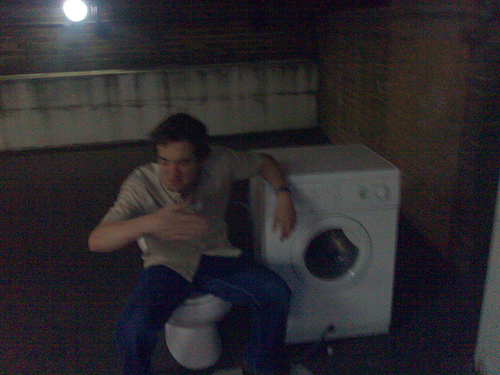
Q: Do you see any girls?
A: No, there are no girls.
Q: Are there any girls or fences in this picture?
A: No, there are no girls or fences.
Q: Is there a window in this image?
A: Yes, there is a window.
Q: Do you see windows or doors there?
A: Yes, there is a window.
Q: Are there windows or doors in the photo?
A: Yes, there is a window.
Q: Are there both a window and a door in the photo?
A: Yes, there are both a window and a door.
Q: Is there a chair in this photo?
A: No, there are no chairs.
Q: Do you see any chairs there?
A: No, there are no chairs.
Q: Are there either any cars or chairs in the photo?
A: No, there are no chairs or cars.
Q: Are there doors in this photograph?
A: Yes, there is a door.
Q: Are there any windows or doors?
A: Yes, there is a door.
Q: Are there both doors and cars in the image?
A: No, there is a door but no cars.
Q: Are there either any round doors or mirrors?
A: Yes, there is a round door.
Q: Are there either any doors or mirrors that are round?
A: Yes, the door is round.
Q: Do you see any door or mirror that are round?
A: Yes, the door is round.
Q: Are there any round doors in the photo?
A: Yes, there is a round door.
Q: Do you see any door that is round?
A: Yes, there is a door that is round.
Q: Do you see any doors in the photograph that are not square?
A: Yes, there is a round door.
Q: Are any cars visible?
A: No, there are no cars.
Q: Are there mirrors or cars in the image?
A: No, there are no cars or mirrors.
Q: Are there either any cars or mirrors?
A: No, there are no cars or mirrors.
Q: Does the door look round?
A: Yes, the door is round.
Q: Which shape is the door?
A: The door is round.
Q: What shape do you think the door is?
A: The door is round.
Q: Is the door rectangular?
A: No, the door is round.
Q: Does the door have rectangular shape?
A: No, the door is round.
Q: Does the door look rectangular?
A: No, the door is round.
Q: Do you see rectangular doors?
A: No, there is a door but it is round.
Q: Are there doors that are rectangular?
A: No, there is a door but it is round.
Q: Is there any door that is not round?
A: No, there is a door but it is round.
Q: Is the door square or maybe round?
A: The door is round.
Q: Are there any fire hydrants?
A: No, there are no fire hydrants.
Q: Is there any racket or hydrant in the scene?
A: No, there are no fire hydrants or rackets.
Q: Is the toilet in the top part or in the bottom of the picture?
A: The toilet is in the bottom of the image.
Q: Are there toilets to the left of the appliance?
A: Yes, there is a toilet to the left of the appliance.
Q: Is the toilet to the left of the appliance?
A: Yes, the toilet is to the left of the appliance.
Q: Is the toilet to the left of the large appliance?
A: Yes, the toilet is to the left of the appliance.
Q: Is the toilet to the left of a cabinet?
A: No, the toilet is to the left of the appliance.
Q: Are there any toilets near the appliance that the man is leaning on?
A: Yes, there is a toilet near the appliance.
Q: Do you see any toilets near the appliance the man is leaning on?
A: Yes, there is a toilet near the appliance.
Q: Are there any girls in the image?
A: No, there are no girls.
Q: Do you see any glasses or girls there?
A: No, there are no girls or glasses.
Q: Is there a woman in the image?
A: No, there are no women.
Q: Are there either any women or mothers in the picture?
A: No, there are no women or mothers.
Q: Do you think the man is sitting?
A: Yes, the man is sitting.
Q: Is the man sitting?
A: Yes, the man is sitting.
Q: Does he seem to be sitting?
A: Yes, the man is sitting.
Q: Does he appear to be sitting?
A: Yes, the man is sitting.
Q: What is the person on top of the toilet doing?
A: The man is sitting.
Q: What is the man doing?
A: The man is sitting.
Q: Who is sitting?
A: The man is sitting.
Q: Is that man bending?
A: No, the man is sitting.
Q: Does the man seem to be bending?
A: No, the man is sitting.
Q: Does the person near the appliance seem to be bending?
A: No, the man is sitting.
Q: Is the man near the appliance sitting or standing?
A: The man is sitting.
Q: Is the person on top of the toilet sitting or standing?
A: The man is sitting.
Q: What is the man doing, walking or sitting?
A: The man is sitting.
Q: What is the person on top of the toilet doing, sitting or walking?
A: The man is sitting.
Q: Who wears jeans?
A: The man wears jeans.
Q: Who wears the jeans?
A: The man wears jeans.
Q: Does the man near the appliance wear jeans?
A: Yes, the man wears jeans.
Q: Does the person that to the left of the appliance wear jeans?
A: Yes, the man wears jeans.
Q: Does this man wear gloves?
A: No, the man wears jeans.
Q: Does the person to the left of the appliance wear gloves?
A: No, the man wears jeans.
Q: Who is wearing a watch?
A: The man is wearing a watch.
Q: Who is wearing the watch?
A: The man is wearing a watch.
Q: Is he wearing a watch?
A: Yes, the man is wearing a watch.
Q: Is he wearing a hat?
A: No, the man is wearing a watch.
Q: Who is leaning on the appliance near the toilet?
A: The man is leaning on the appliance.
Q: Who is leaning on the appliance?
A: The man is leaning on the appliance.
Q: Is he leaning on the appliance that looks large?
A: Yes, the man is leaning on the appliance.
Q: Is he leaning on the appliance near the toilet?
A: Yes, the man is leaning on the appliance.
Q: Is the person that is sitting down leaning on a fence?
A: No, the man is leaning on the appliance.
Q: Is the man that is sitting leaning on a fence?
A: No, the man is leaning on the appliance.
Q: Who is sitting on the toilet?
A: The man is sitting on the toilet.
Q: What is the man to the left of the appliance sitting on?
A: The man is sitting on the toilet.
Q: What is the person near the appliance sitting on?
A: The man is sitting on the toilet.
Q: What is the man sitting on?
A: The man is sitting on the toilet.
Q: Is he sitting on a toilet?
A: Yes, the man is sitting on a toilet.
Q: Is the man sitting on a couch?
A: No, the man is sitting on a toilet.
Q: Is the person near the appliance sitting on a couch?
A: No, the man is sitting on a toilet.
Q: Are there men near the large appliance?
A: Yes, there is a man near the appliance.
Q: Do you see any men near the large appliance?
A: Yes, there is a man near the appliance.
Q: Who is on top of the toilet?
A: The man is on top of the toilet.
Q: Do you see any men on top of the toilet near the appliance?
A: Yes, there is a man on top of the toilet.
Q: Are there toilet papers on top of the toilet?
A: No, there is a man on top of the toilet.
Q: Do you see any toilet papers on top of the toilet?
A: No, there is a man on top of the toilet.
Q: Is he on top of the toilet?
A: Yes, the man is on top of the toilet.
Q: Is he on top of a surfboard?
A: No, the man is on top of the toilet.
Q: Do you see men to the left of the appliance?
A: Yes, there is a man to the left of the appliance.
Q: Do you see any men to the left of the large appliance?
A: Yes, there is a man to the left of the appliance.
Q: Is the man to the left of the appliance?
A: Yes, the man is to the left of the appliance.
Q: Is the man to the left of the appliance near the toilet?
A: Yes, the man is to the left of the appliance.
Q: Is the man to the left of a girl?
A: No, the man is to the left of the appliance.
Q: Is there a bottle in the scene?
A: No, there are no bottles.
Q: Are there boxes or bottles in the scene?
A: No, there are no bottles or boxes.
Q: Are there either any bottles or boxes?
A: No, there are no bottles or boxes.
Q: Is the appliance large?
A: Yes, the appliance is large.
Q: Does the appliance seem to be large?
A: Yes, the appliance is large.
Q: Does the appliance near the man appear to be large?
A: Yes, the appliance is large.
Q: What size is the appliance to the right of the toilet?
A: The appliance is large.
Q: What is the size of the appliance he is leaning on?
A: The appliance is large.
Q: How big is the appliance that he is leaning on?
A: The appliance is large.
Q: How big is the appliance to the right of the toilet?
A: The appliance is large.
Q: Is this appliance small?
A: No, the appliance is large.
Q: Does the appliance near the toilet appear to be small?
A: No, the appliance is large.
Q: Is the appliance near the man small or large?
A: The appliance is large.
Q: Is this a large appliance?
A: Yes, this is a large appliance.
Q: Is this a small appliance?
A: No, this is a large appliance.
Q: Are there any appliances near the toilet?
A: Yes, there is an appliance near the toilet.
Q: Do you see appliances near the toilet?
A: Yes, there is an appliance near the toilet.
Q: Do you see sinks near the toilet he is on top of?
A: No, there is an appliance near the toilet.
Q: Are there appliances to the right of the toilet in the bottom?
A: Yes, there is an appliance to the right of the toilet.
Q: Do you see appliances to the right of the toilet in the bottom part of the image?
A: Yes, there is an appliance to the right of the toilet.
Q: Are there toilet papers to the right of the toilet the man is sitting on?
A: No, there is an appliance to the right of the toilet.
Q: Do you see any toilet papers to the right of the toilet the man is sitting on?
A: No, there is an appliance to the right of the toilet.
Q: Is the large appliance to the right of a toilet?
A: Yes, the appliance is to the right of a toilet.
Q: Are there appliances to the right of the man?
A: Yes, there is an appliance to the right of the man.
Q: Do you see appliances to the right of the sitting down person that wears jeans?
A: Yes, there is an appliance to the right of the man.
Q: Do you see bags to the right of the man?
A: No, there is an appliance to the right of the man.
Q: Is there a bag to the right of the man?
A: No, there is an appliance to the right of the man.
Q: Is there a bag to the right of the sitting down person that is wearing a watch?
A: No, there is an appliance to the right of the man.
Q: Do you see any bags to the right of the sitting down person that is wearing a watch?
A: No, there is an appliance to the right of the man.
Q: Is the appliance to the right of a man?
A: Yes, the appliance is to the right of a man.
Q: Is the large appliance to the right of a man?
A: Yes, the appliance is to the right of a man.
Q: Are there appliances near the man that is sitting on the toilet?
A: Yes, there is an appliance near the man.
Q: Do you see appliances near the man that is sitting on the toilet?
A: Yes, there is an appliance near the man.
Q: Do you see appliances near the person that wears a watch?
A: Yes, there is an appliance near the man.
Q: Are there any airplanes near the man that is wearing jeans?
A: No, there is an appliance near the man.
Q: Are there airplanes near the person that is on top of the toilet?
A: No, there is an appliance near the man.